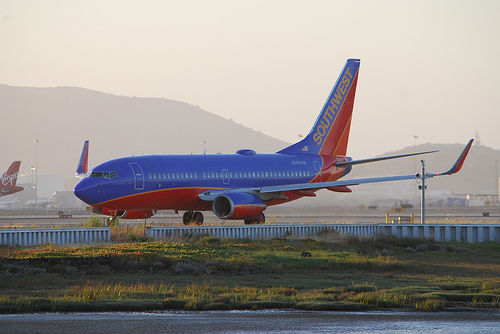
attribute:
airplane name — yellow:
[311, 63, 357, 147]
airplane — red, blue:
[71, 57, 484, 235]